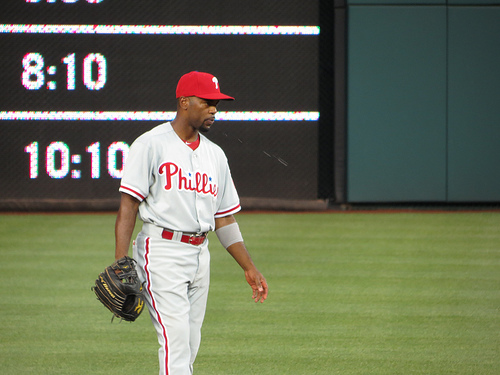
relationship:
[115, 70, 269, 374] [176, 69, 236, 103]
man wearing cap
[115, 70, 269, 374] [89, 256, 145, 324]
man holding glove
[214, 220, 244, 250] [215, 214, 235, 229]
band around elbow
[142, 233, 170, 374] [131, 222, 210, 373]
stripe on side of pants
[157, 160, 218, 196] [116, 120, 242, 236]
team name on front of jersey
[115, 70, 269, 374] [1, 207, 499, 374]
man standing on field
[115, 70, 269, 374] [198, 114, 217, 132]
man has facial hair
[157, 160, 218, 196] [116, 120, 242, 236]
team name written on front of jersey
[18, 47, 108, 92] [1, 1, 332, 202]
time lit on scoreboard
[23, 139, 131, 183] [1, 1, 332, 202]
time lit on scoreboard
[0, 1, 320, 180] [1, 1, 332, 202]
lights on front of scoreboard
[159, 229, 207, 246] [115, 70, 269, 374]
belt around man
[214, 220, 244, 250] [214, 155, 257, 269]
band around left arm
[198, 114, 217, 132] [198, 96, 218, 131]
facial hair on front of face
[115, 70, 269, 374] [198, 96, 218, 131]
man has face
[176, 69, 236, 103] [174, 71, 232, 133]
cap covering head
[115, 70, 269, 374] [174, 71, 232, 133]
man has head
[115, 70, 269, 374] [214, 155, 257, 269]
man has left arm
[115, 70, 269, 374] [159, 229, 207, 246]
man wearing belt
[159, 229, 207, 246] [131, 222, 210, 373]
belt supporting pants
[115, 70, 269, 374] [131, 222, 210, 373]
man wearing pants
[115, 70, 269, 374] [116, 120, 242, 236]
man wearing jersey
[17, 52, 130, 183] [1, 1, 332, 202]
numbers displayed on scoreboard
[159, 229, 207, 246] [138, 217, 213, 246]
belt around waist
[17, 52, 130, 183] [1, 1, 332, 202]
numbers on front of scoreboard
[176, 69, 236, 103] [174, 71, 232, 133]
cap on top of head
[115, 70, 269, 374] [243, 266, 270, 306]
man has hand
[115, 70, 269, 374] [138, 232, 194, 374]
man has leg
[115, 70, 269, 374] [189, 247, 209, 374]
man has leg